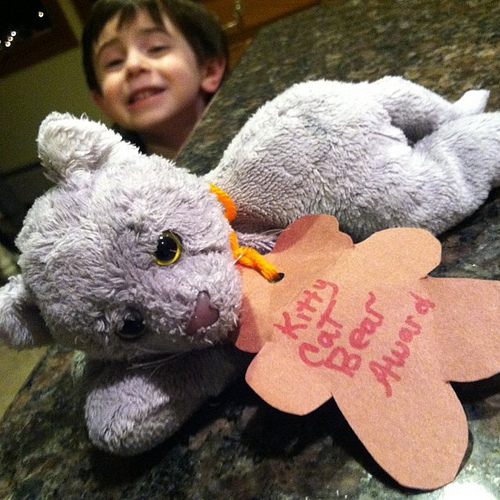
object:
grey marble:
[0, 406, 83, 499]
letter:
[272, 310, 308, 340]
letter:
[298, 341, 324, 367]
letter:
[408, 291, 436, 315]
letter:
[365, 291, 386, 319]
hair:
[79, 0, 230, 103]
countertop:
[0, 0, 500, 500]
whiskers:
[123, 352, 195, 414]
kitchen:
[2, 2, 500, 500]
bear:
[324, 291, 384, 378]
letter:
[392, 340, 410, 360]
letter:
[317, 300, 343, 329]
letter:
[323, 347, 361, 376]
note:
[232, 214, 499, 490]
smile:
[104, 40, 173, 108]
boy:
[80, 0, 229, 158]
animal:
[0, 74, 500, 456]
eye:
[149, 231, 181, 265]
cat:
[298, 299, 343, 367]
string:
[209, 182, 283, 281]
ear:
[35, 110, 118, 182]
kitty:
[274, 278, 338, 342]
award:
[274, 279, 434, 399]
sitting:
[202, 376, 248, 417]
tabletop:
[0, 0, 500, 500]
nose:
[185, 289, 220, 334]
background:
[0, 0, 499, 90]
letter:
[367, 361, 402, 398]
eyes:
[114, 307, 146, 340]